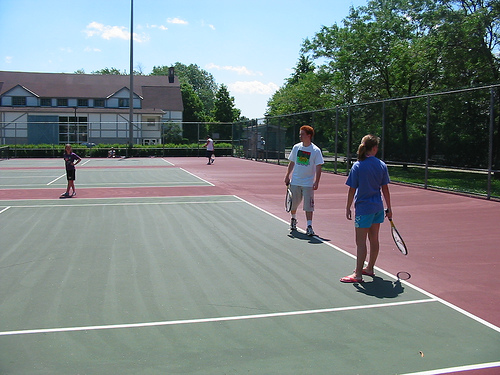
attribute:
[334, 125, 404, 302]
person — woman, standing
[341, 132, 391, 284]
person — standing, woman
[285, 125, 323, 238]
person — standing, man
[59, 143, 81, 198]
person — standing, woman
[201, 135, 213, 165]
person — standing, man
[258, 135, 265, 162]
person — standing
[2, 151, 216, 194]
court — green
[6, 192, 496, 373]
court — green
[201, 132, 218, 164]
person — standing, man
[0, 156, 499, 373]
tennis court — green, maroon, concrete, painted, hard, clean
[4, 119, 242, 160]
fence — closed, metal, chain, standing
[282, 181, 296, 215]
tennis racket — black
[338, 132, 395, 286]
person — woman, standing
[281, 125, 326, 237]
person — man, standing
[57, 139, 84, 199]
person — woman, standing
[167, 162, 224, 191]
line — white, straight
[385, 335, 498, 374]
line — white, straight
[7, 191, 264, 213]
line — white, straight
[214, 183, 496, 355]
line — white, straight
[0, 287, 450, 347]
line — white, straight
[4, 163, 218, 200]
court — green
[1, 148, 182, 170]
court — green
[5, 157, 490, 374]
court — green, concrete, painted, rectangle, hard, clean, paved, green and red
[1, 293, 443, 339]
line — white, painted, straight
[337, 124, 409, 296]
tennis player — male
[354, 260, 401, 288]
flip flops — pink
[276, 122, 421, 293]
people — standing, holding, dressed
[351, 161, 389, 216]
shirt — blue, short sleeve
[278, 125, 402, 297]
people — dressed, standing, holding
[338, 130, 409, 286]
female — dressed, standing, holding, looking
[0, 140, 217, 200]
court — green and red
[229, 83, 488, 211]
fence — chain, metal, standing, closed